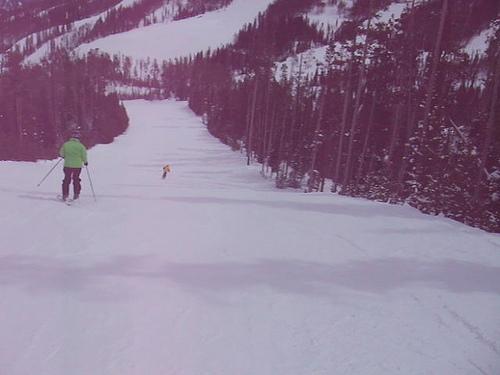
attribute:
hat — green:
[67, 125, 84, 137]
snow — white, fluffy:
[0, 0, 498, 373]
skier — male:
[55, 123, 93, 207]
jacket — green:
[59, 140, 93, 168]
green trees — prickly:
[2, 56, 132, 170]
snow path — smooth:
[116, 95, 259, 374]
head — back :
[68, 126, 81, 146]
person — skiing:
[56, 130, 85, 200]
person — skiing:
[162, 157, 170, 183]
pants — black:
[59, 162, 86, 197]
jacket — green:
[56, 127, 93, 207]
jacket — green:
[56, 137, 92, 174]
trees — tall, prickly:
[254, 58, 415, 178]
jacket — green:
[60, 134, 87, 169]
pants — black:
[56, 166, 86, 196]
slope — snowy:
[164, 4, 499, 205]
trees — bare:
[250, 66, 370, 163]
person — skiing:
[52, 126, 92, 201]